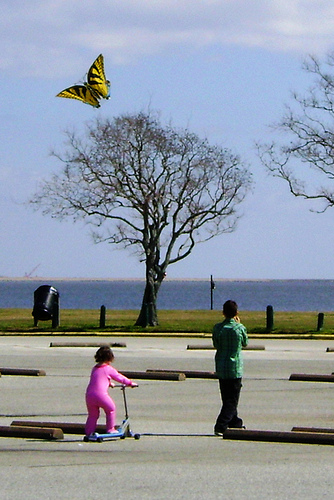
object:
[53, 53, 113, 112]
butterfly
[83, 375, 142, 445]
scooter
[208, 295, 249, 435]
boy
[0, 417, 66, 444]
bumps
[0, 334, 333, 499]
parking lot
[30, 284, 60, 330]
can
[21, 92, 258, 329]
trees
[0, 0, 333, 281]
sky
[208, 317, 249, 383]
shirt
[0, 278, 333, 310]
water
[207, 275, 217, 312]
pole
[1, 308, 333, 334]
grass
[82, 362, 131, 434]
jumper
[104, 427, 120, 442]
feet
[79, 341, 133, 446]
kids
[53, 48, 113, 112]
kite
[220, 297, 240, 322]
hair